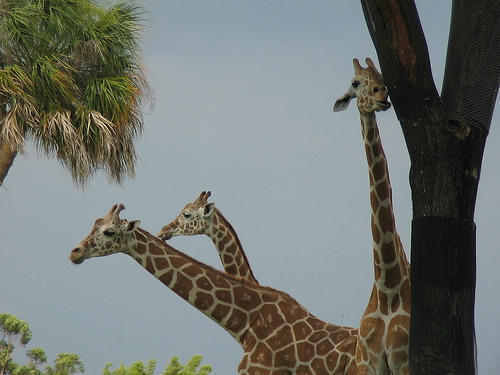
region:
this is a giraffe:
[20, 206, 378, 371]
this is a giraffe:
[148, 175, 283, 305]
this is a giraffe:
[345, 48, 425, 370]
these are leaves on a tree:
[25, 39, 82, 99]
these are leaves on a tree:
[61, 19, 103, 74]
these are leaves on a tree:
[52, 113, 120, 183]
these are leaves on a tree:
[45, 23, 103, 124]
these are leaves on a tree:
[84, 72, 128, 152]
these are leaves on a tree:
[10, 311, 52, 372]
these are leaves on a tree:
[160, 356, 215, 371]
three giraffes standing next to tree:
[64, 43, 414, 371]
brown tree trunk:
[382, 109, 498, 374]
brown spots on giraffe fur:
[255, 318, 306, 361]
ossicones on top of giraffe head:
[103, 196, 133, 216]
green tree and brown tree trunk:
[1, 0, 146, 202]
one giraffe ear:
[327, 88, 354, 115]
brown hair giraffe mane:
[215, 212, 262, 280]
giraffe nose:
[65, 243, 85, 259]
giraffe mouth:
[68, 248, 90, 270]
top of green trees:
[1, 307, 218, 374]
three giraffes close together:
[101, 73, 431, 373]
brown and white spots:
[194, 241, 350, 369]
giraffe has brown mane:
[149, 212, 291, 321]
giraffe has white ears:
[127, 202, 148, 241]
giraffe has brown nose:
[63, 238, 86, 280]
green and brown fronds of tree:
[4, 2, 129, 180]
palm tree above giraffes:
[11, 13, 143, 198]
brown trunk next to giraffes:
[354, 20, 495, 373]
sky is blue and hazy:
[172, 16, 297, 156]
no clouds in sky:
[170, 0, 297, 153]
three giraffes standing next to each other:
[61, 38, 423, 373]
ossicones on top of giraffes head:
[97, 193, 133, 215]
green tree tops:
[1, 1, 148, 202]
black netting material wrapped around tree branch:
[436, 1, 498, 141]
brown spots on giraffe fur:
[219, 300, 269, 326]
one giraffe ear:
[198, 197, 220, 221]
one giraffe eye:
[99, 224, 124, 240]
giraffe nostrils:
[67, 244, 85, 254]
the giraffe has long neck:
[104, 223, 264, 345]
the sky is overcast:
[179, 58, 279, 171]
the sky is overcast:
[217, 97, 316, 222]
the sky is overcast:
[153, 22, 321, 191]